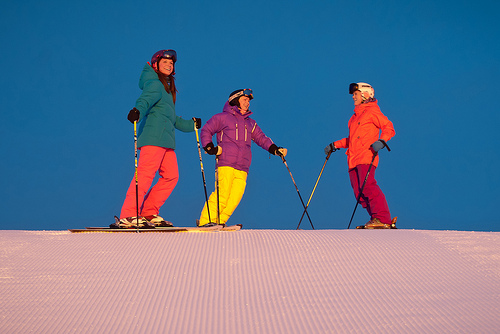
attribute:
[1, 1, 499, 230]
sky — bright, blue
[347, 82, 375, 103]
helmet — white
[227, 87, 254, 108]
helmet — black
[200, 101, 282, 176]
coat — purple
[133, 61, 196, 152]
coat — green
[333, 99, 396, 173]
jacket — orange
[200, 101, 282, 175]
parka — purple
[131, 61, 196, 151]
jacket — teal, blue, gree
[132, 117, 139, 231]
ski pole — multicolored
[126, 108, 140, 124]
glove — black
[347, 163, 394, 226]
pants — purple, red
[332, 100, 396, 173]
coat — orange, bright orange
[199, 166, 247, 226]
pants — bright yellow, yellow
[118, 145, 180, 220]
pants — peach colored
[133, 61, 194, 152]
winter coat — green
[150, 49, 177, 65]
helmet — purple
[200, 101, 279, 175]
jacket — purple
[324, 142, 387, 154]
gloves — grey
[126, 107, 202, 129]
gloves — black